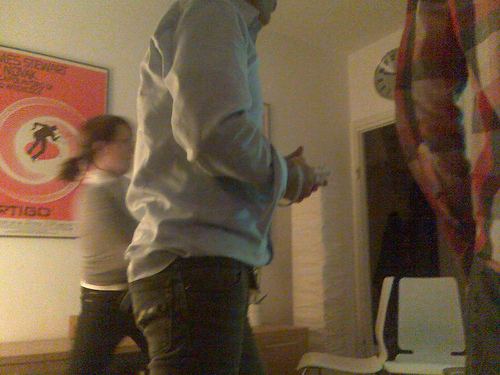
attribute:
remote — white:
[278, 157, 334, 203]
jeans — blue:
[151, 228, 263, 374]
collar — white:
[84, 163, 119, 195]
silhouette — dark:
[26, 122, 58, 160]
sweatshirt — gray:
[122, 2, 292, 288]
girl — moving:
[57, 103, 204, 372]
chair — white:
[367, 252, 467, 363]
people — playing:
[76, 0, 336, 374]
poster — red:
[0, 44, 110, 238]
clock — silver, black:
[371, 44, 408, 102]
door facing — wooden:
[350, 126, 372, 357]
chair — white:
[387, 276, 469, 372]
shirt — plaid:
[393, 1, 498, 274]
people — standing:
[56, 3, 497, 372]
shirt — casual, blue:
[99, 31, 309, 307]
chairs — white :
[383, 275, 470, 374]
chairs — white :
[294, 273, 397, 372]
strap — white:
[278, 160, 303, 207]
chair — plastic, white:
[384, 272, 466, 370]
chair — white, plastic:
[296, 272, 398, 369]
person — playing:
[132, 0, 320, 372]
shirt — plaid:
[68, 151, 190, 296]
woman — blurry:
[59, 110, 160, 373]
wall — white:
[2, 3, 124, 283]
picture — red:
[0, 43, 119, 237]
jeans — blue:
[123, 243, 263, 370]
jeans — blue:
[58, 269, 136, 365]